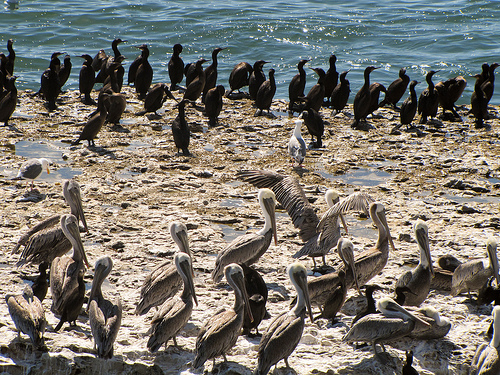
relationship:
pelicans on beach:
[213, 68, 307, 102] [141, 171, 210, 184]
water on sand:
[376, 35, 381, 36] [111, 137, 123, 145]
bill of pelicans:
[121, 38, 129, 46] [213, 68, 307, 102]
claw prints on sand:
[132, 172, 201, 213] [111, 137, 123, 145]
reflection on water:
[248, 29, 259, 36] [376, 35, 381, 36]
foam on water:
[465, 16, 480, 51] [376, 35, 381, 36]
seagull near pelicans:
[129, 223, 203, 359] [213, 68, 307, 102]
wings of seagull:
[249, 165, 366, 223] [129, 223, 203, 359]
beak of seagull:
[384, 219, 398, 250] [129, 223, 203, 359]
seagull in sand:
[129, 223, 203, 359] [111, 137, 123, 145]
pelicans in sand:
[213, 68, 307, 102] [111, 137, 123, 145]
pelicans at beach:
[213, 68, 307, 102] [141, 171, 210, 184]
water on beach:
[376, 35, 381, 36] [141, 171, 210, 184]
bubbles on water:
[62, 78, 70, 99] [376, 35, 381, 36]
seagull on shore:
[129, 223, 203, 359] [309, 123, 410, 178]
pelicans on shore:
[213, 68, 307, 102] [309, 123, 410, 178]